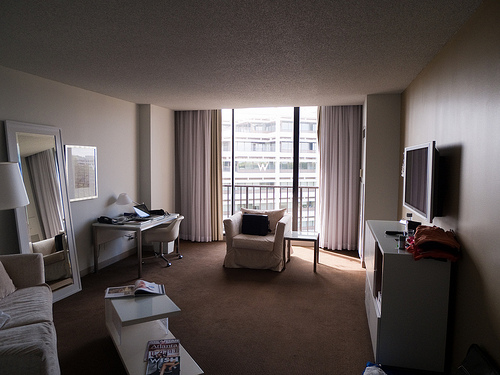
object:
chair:
[222, 207, 292, 273]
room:
[1, 0, 500, 374]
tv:
[401, 140, 452, 224]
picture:
[62, 144, 98, 203]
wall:
[64, 104, 134, 142]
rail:
[222, 185, 318, 189]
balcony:
[222, 185, 317, 234]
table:
[283, 231, 320, 273]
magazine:
[104, 279, 166, 299]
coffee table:
[104, 280, 206, 374]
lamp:
[0, 162, 30, 211]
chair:
[0, 252, 63, 374]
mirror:
[3, 118, 84, 305]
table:
[91, 213, 180, 279]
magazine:
[143, 339, 181, 375]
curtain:
[177, 109, 223, 242]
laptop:
[132, 204, 164, 221]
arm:
[223, 211, 242, 237]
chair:
[142, 215, 184, 267]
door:
[223, 105, 319, 235]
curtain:
[316, 106, 361, 252]